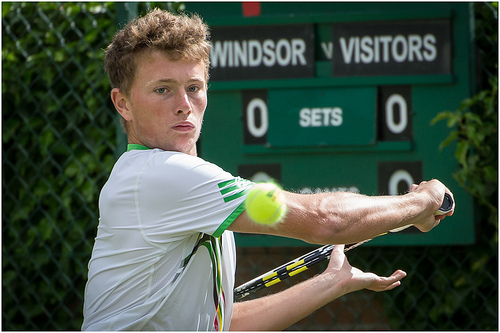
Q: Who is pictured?
A: A tennis player.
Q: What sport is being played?
A: Tennis.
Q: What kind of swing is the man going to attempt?
A: A backhand.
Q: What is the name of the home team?
A: "Windsor".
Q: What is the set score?
A: 0-0.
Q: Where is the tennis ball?
A: In the air.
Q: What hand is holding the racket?
A: The right hand.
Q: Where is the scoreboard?
A: On the fence.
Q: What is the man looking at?
A: A tennis ball.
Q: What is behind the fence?
A: Vegetation.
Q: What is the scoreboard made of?
A: Wood.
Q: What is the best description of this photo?
A: A young man looks at a yellow tennis ball.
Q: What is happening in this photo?
A: A young man is hitting the tennis ball.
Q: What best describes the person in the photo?
A: Young man with light brown/dark blonde hair.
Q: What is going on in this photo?
A: A man watching a tennis ball approach him.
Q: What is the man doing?
A: Getting ready to swing a tennis racket.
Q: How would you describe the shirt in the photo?
A: White shirt with green edging around the neck and arm.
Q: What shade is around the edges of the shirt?
A: Green around neck and sleeves.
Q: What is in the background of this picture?
A: Scoreboard.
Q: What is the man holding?
A: Black and yellow tennis racket.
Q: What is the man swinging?
A: A black and yellow tennis racquet?.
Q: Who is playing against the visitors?
A: Windsor.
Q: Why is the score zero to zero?
A: No sets have been finished.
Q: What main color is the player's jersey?
A: White.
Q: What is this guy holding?
A: Tennis racket.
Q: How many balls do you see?
A: 1.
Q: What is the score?
A: 0 - 0.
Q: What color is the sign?
A: Green and white and black.